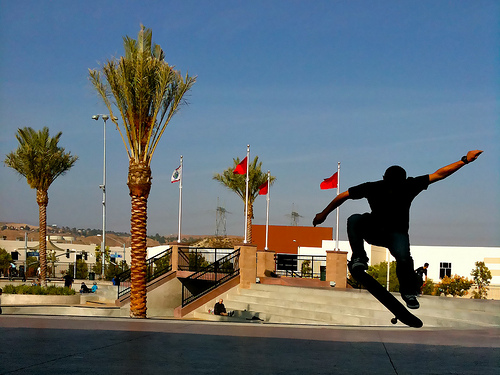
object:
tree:
[88, 17, 198, 320]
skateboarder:
[311, 148, 489, 310]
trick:
[311, 147, 482, 328]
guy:
[212, 297, 229, 317]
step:
[207, 282, 344, 326]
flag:
[320, 172, 339, 189]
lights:
[92, 111, 118, 125]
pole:
[100, 113, 108, 280]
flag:
[233, 155, 249, 175]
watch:
[460, 155, 470, 164]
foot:
[400, 290, 419, 310]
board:
[346, 263, 424, 329]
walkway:
[127, 278, 217, 319]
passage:
[170, 244, 252, 275]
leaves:
[89, 67, 127, 115]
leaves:
[83, 20, 199, 158]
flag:
[258, 182, 270, 195]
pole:
[333, 159, 342, 252]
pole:
[243, 142, 252, 247]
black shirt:
[350, 173, 433, 237]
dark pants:
[347, 214, 416, 294]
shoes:
[350, 258, 422, 309]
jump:
[311, 147, 484, 326]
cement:
[199, 311, 232, 323]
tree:
[2, 123, 79, 286]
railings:
[273, 251, 328, 280]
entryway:
[240, 243, 348, 291]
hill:
[0, 220, 253, 247]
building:
[409, 244, 498, 287]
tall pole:
[97, 111, 110, 279]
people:
[80, 280, 100, 293]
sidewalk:
[0, 311, 499, 373]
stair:
[194, 282, 499, 329]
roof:
[250, 224, 335, 255]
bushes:
[2, 283, 81, 303]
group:
[3, 282, 78, 295]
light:
[91, 113, 117, 279]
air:
[254, 83, 498, 341]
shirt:
[215, 302, 226, 310]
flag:
[170, 164, 182, 184]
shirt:
[90, 283, 100, 292]